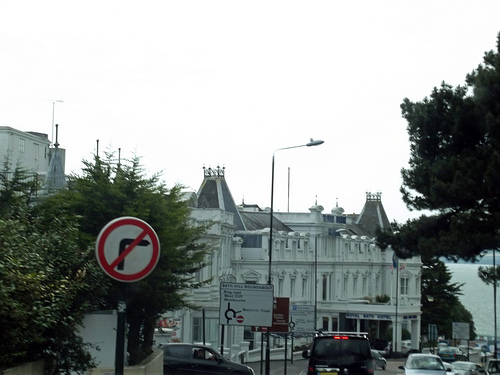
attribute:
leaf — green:
[16, 223, 23, 230]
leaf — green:
[429, 139, 440, 168]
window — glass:
[295, 236, 301, 248]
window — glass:
[284, 237, 290, 252]